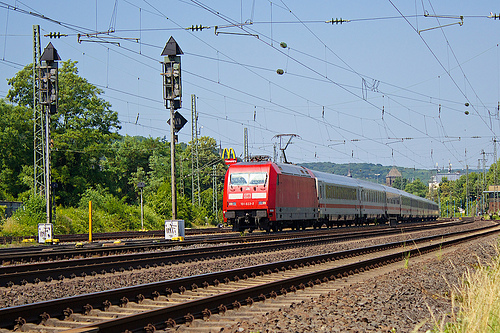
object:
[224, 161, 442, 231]
train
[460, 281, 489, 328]
grass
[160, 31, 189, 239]
pole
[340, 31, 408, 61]
sky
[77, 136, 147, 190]
trees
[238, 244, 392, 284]
tracks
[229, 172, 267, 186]
windshield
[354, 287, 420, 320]
gravel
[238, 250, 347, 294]
track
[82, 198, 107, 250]
pole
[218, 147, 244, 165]
sign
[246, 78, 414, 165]
wires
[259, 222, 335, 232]
wheels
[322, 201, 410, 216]
stripe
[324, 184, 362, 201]
windows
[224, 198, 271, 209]
headlights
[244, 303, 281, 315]
wood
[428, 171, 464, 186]
roof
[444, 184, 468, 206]
trees